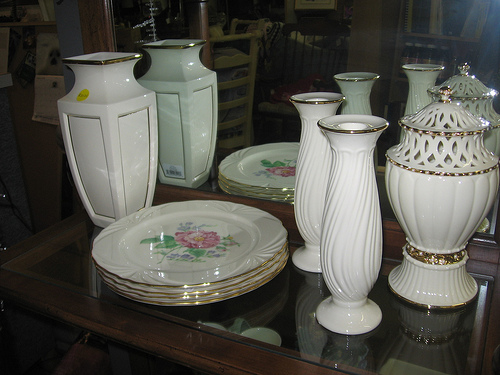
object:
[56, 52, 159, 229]
vase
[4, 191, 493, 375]
table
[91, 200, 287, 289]
plates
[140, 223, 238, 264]
floral pattern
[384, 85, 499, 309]
vase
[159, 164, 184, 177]
bar code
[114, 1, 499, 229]
mirror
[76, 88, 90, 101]
sticker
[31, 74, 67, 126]
calendar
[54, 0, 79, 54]
wall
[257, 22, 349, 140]
chair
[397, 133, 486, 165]
design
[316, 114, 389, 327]
vase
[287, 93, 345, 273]
vase